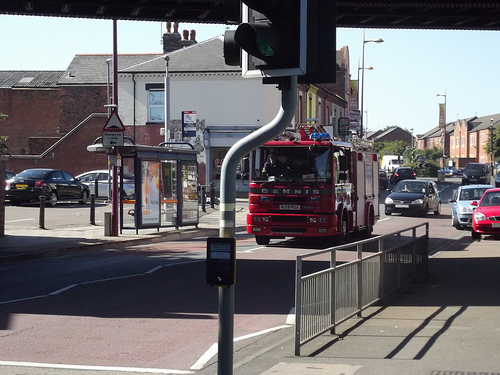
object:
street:
[396, 269, 498, 370]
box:
[204, 234, 236, 287]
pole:
[215, 77, 299, 367]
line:
[166, 255, 206, 267]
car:
[75, 162, 140, 200]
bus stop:
[86, 134, 201, 237]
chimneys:
[161, 20, 184, 51]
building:
[0, 20, 227, 182]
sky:
[376, 22, 499, 86]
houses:
[415, 113, 498, 174]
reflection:
[299, 264, 469, 364]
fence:
[292, 220, 430, 357]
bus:
[243, 123, 382, 245]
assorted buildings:
[0, 43, 365, 194]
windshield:
[252, 146, 333, 183]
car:
[448, 184, 497, 231]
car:
[390, 167, 417, 186]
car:
[462, 161, 492, 186]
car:
[469, 187, 500, 242]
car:
[382, 179, 442, 216]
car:
[5, 167, 90, 208]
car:
[71, 169, 136, 200]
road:
[3, 189, 494, 371]